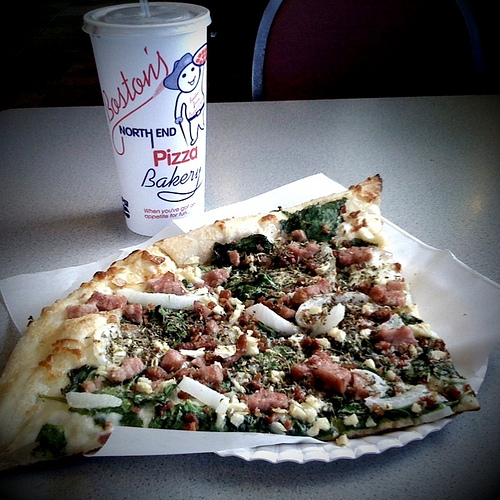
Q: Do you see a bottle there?
A: No, there are no bottles.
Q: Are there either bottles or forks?
A: No, there are no bottles or forks.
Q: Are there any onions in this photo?
A: Yes, there is an onion.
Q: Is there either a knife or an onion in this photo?
A: Yes, there is an onion.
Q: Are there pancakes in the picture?
A: No, there are no pancakes.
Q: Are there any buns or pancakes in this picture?
A: No, there are no pancakes or buns.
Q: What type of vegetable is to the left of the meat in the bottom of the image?
A: The vegetable is an onion.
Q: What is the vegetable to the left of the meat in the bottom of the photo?
A: The vegetable is an onion.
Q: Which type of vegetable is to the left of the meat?
A: The vegetable is an onion.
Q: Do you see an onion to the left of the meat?
A: Yes, there is an onion to the left of the meat.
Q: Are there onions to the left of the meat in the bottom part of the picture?
A: Yes, there is an onion to the left of the meat.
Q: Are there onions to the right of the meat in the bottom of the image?
A: No, the onion is to the left of the meat.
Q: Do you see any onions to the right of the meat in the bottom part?
A: No, the onion is to the left of the meat.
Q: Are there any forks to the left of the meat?
A: No, there is an onion to the left of the meat.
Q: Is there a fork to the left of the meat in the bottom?
A: No, there is an onion to the left of the meat.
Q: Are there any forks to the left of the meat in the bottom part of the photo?
A: No, there is an onion to the left of the meat.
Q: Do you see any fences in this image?
A: No, there are no fences.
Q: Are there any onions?
A: Yes, there are onions.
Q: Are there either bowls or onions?
A: Yes, there are onions.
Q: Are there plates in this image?
A: Yes, there is a plate.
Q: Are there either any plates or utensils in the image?
A: Yes, there is a plate.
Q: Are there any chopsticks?
A: No, there are no chopsticks.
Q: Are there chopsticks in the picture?
A: No, there are no chopsticks.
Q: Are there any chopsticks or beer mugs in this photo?
A: No, there are no chopsticks or beer mugs.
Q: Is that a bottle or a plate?
A: That is a plate.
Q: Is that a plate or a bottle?
A: That is a plate.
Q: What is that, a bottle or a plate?
A: That is a plate.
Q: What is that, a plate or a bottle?
A: That is a plate.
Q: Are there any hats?
A: Yes, there is a hat.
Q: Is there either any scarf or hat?
A: Yes, there is a hat.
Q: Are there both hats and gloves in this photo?
A: No, there is a hat but no gloves.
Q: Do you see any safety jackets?
A: No, there are no safety jackets.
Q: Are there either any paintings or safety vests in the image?
A: No, there are no safety vests or paintings.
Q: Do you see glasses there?
A: No, there are no glasses.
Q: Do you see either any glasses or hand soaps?
A: No, there are no glasses or hand soaps.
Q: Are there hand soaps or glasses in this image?
A: No, there are no glasses or hand soaps.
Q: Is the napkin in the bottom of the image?
A: Yes, the napkin is in the bottom of the image.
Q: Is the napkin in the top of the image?
A: No, the napkin is in the bottom of the image.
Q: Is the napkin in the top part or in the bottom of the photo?
A: The napkin is in the bottom of the image.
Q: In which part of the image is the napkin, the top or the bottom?
A: The napkin is in the bottom of the image.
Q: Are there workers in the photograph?
A: No, there are no workers.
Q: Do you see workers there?
A: No, there are no workers.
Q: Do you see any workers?
A: No, there are no workers.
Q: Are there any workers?
A: No, there are no workers.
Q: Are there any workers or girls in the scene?
A: No, there are no workers or girls.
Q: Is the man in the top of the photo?
A: Yes, the man is in the top of the image.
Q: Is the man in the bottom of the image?
A: No, the man is in the top of the image.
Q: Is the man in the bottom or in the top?
A: The man is in the top of the image.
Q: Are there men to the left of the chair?
A: Yes, there is a man to the left of the chair.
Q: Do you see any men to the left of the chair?
A: Yes, there is a man to the left of the chair.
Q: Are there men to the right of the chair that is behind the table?
A: No, the man is to the left of the chair.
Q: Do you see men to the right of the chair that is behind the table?
A: No, the man is to the left of the chair.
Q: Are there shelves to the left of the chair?
A: No, there is a man to the left of the chair.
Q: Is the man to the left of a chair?
A: Yes, the man is to the left of a chair.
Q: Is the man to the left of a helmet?
A: No, the man is to the left of a chair.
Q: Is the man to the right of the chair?
A: No, the man is to the left of the chair.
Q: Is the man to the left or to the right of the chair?
A: The man is to the left of the chair.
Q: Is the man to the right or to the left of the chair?
A: The man is to the left of the chair.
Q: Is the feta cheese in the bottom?
A: Yes, the feta cheese is in the bottom of the image.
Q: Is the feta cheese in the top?
A: No, the feta cheese is in the bottom of the image.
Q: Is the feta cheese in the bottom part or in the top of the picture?
A: The feta cheese is in the bottom of the image.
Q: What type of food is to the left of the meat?
A: The food is feta cheese.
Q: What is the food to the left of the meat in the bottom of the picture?
A: The food is feta cheese.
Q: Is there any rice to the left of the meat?
A: No, there is feta cheese to the left of the meat.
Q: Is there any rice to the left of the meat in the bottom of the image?
A: No, there is feta cheese to the left of the meat.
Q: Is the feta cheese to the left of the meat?
A: Yes, the feta cheese is to the left of the meat.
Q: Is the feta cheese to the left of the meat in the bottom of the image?
A: Yes, the feta cheese is to the left of the meat.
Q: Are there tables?
A: Yes, there is a table.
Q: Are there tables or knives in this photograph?
A: Yes, there is a table.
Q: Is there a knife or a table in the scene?
A: Yes, there is a table.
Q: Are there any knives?
A: No, there are no knives.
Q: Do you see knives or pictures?
A: No, there are no knives or pictures.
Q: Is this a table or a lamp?
A: This is a table.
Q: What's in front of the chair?
A: The table is in front of the chair.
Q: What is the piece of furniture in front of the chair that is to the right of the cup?
A: The piece of furniture is a table.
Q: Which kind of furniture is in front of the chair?
A: The piece of furniture is a table.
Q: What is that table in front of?
A: The table is in front of the chair.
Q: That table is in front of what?
A: The table is in front of the chair.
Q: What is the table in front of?
A: The table is in front of the chair.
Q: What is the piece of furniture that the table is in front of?
A: The piece of furniture is a chair.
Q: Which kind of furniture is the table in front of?
A: The table is in front of the chair.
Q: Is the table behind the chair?
A: No, the table is in front of the chair.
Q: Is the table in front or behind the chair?
A: The table is in front of the chair.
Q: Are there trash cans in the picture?
A: No, there are no trash cans.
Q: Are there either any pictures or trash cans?
A: No, there are no trash cans or pictures.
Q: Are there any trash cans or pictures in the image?
A: No, there are no trash cans or pictures.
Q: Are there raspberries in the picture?
A: No, there are no raspberries.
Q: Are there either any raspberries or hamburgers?
A: No, there are no raspberries or hamburgers.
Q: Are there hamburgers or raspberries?
A: No, there are no raspberries or hamburgers.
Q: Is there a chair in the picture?
A: Yes, there is a chair.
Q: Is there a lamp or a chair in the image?
A: Yes, there is a chair.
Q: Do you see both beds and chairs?
A: No, there is a chair but no beds.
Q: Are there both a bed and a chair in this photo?
A: No, there is a chair but no beds.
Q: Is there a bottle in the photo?
A: No, there are no bottles.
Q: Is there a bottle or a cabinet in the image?
A: No, there are no bottles or cabinets.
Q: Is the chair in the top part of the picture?
A: Yes, the chair is in the top of the image.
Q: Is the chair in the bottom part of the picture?
A: No, the chair is in the top of the image.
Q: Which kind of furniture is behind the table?
A: The piece of furniture is a chair.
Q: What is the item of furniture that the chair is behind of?
A: The piece of furniture is a table.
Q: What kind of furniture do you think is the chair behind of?
A: The chair is behind the table.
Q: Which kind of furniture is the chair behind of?
A: The chair is behind the table.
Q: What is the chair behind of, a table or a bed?
A: The chair is behind a table.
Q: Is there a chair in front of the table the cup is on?
A: No, the chair is behind the table.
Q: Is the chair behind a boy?
A: No, the chair is behind a table.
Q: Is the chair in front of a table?
A: No, the chair is behind a table.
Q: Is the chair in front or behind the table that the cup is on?
A: The chair is behind the table.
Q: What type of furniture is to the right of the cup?
A: The piece of furniture is a chair.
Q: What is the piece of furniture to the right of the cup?
A: The piece of furniture is a chair.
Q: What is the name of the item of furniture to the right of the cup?
A: The piece of furniture is a chair.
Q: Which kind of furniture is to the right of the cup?
A: The piece of furniture is a chair.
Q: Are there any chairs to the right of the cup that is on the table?
A: Yes, there is a chair to the right of the cup.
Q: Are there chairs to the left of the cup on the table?
A: No, the chair is to the right of the cup.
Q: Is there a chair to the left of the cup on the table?
A: No, the chair is to the right of the cup.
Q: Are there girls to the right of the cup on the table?
A: No, there is a chair to the right of the cup.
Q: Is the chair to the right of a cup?
A: Yes, the chair is to the right of a cup.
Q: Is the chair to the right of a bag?
A: No, the chair is to the right of a cup.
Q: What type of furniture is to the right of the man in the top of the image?
A: The piece of furniture is a chair.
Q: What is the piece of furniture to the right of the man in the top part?
A: The piece of furniture is a chair.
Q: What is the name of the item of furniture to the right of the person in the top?
A: The piece of furniture is a chair.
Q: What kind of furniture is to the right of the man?
A: The piece of furniture is a chair.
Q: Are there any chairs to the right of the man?
A: Yes, there is a chair to the right of the man.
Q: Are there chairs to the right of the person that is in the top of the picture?
A: Yes, there is a chair to the right of the man.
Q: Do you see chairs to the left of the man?
A: No, the chair is to the right of the man.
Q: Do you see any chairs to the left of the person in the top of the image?
A: No, the chair is to the right of the man.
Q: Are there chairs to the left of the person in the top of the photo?
A: No, the chair is to the right of the man.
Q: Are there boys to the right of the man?
A: No, there is a chair to the right of the man.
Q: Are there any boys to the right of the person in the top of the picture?
A: No, there is a chair to the right of the man.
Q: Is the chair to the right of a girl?
A: No, the chair is to the right of a man.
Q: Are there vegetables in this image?
A: Yes, there are vegetables.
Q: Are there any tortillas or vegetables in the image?
A: Yes, there are vegetables.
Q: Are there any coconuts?
A: No, there are no coconuts.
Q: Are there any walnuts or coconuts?
A: No, there are no coconuts or walnuts.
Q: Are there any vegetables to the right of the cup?
A: Yes, there are vegetables to the right of the cup.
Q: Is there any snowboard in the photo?
A: No, there are no snowboards.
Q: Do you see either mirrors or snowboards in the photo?
A: No, there are no snowboards or mirrors.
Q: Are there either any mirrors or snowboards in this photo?
A: No, there are no snowboards or mirrors.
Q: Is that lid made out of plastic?
A: Yes, the lid is made of plastic.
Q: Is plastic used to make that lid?
A: Yes, the lid is made of plastic.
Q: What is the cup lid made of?
A: The lid is made of plastic.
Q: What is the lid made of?
A: The lid is made of plastic.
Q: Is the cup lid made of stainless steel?
A: No, the lid is made of plastic.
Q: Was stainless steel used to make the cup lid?
A: No, the lid is made of plastic.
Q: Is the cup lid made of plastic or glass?
A: The lid is made of plastic.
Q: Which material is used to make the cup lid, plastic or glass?
A: The lid is made of plastic.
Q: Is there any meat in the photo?
A: Yes, there is meat.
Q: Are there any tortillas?
A: No, there are no tortillas.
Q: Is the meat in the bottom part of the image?
A: Yes, the meat is in the bottom of the image.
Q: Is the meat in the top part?
A: No, the meat is in the bottom of the image.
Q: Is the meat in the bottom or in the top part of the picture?
A: The meat is in the bottom of the image.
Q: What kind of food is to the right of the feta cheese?
A: The food is meat.